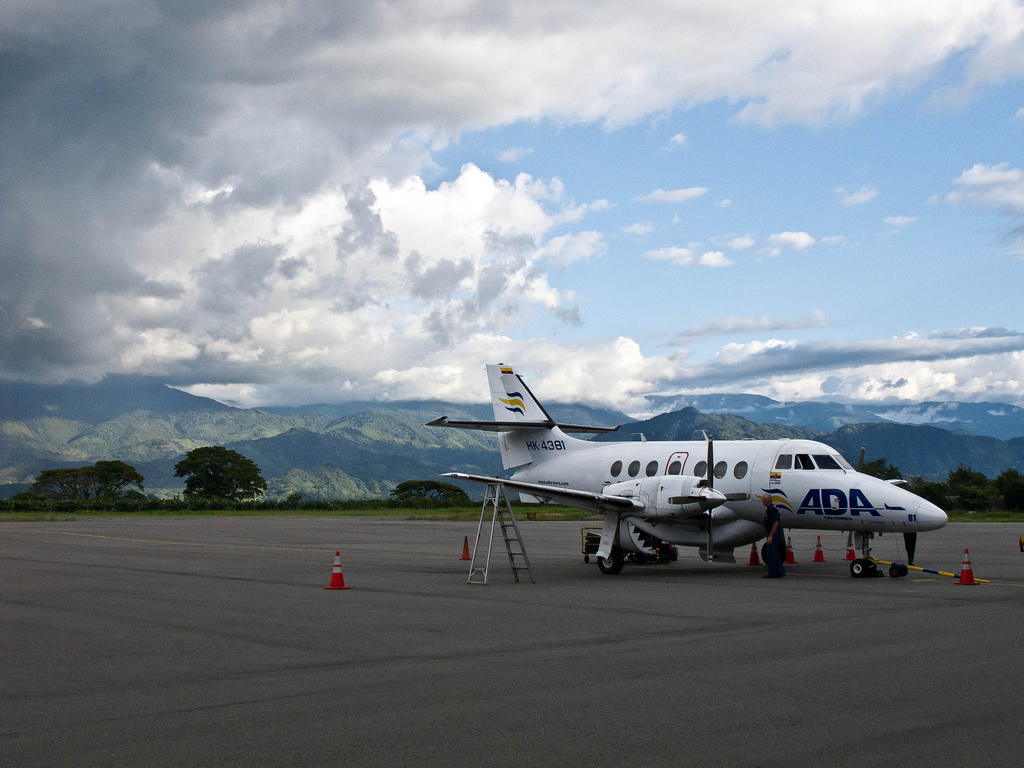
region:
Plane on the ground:
[428, 352, 961, 577]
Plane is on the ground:
[412, 345, 964, 584]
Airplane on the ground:
[425, 326, 961, 589]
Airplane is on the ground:
[413, 339, 946, 596]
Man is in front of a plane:
[740, 471, 804, 598]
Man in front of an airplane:
[738, 482, 811, 584]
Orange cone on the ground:
[310, 545, 368, 597]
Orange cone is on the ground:
[314, 539, 359, 606]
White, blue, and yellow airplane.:
[426, 361, 995, 590]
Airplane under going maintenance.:
[420, 348, 996, 596]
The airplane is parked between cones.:
[423, 351, 993, 602]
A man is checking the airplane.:
[422, 342, 1004, 596]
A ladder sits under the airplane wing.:
[435, 355, 989, 584]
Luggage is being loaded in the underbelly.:
[416, 357, 990, 595]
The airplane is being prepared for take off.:
[424, 353, 998, 595]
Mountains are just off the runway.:
[422, 347, 1002, 592]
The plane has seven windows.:
[424, 345, 997, 595]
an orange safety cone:
[331, 537, 361, 614]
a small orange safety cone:
[438, 537, 484, 567]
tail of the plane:
[476, 350, 575, 475]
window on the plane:
[606, 453, 627, 501]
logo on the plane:
[783, 480, 886, 526]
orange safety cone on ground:
[950, 537, 976, 596]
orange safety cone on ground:
[831, 532, 864, 571]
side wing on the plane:
[436, 461, 642, 537]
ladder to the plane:
[471, 483, 545, 594]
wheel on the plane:
[590, 537, 625, 579]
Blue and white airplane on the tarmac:
[410, 334, 943, 581]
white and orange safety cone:
[318, 549, 353, 585]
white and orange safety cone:
[954, 544, 980, 587]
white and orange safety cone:
[814, 528, 827, 564]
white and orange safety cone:
[458, 527, 477, 554]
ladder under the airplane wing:
[462, 473, 532, 581]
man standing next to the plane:
[754, 483, 794, 573]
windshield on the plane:
[776, 443, 853, 475]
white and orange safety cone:
[809, 524, 828, 566]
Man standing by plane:
[431, 363, 950, 583]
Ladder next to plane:
[425, 364, 938, 586]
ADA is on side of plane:
[440, 360, 946, 582]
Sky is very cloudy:
[4, 0, 1016, 428]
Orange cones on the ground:
[1, 506, 1013, 762]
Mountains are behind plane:
[0, 373, 1016, 579]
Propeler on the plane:
[449, 361, 943, 581]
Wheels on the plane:
[435, 357, 947, 582]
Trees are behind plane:
[1, 445, 1022, 575]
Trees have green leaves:
[4, 446, 1017, 517]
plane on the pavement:
[451, 352, 941, 584]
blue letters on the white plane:
[793, 472, 888, 520]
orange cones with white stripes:
[319, 519, 981, 589]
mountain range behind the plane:
[16, 377, 1020, 499]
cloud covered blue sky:
[15, 3, 1022, 412]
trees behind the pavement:
[29, 433, 1012, 509]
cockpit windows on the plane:
[783, 444, 841, 480]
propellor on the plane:
[672, 433, 745, 550]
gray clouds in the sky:
[10, 12, 602, 387]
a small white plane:
[436, 385, 943, 567]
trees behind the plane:
[49, 454, 256, 499]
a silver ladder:
[473, 487, 527, 576]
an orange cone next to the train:
[325, 549, 352, 587]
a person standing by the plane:
[757, 493, 781, 560]